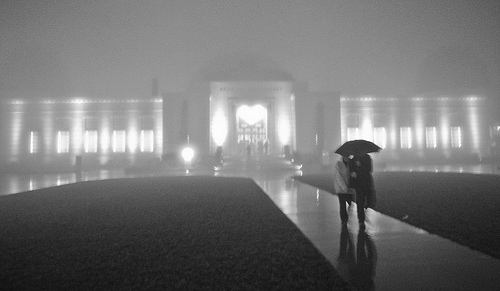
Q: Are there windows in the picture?
A: Yes, there is a window.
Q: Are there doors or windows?
A: Yes, there is a window.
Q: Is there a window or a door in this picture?
A: Yes, there is a window.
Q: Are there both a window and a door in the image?
A: Yes, there are both a window and a door.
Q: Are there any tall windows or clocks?
A: Yes, there is a tall window.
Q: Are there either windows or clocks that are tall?
A: Yes, the window is tall.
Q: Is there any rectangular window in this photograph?
A: Yes, there is a rectangular window.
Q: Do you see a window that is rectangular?
A: Yes, there is a window that is rectangular.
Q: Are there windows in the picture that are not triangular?
A: Yes, there is a rectangular window.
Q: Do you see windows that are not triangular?
A: Yes, there is a rectangular window.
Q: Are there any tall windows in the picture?
A: Yes, there is a tall window.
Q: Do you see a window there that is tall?
A: Yes, there is a window that is tall.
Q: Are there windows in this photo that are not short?
A: Yes, there is a tall window.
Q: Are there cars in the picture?
A: No, there are no cars.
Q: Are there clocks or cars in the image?
A: No, there are no cars or clocks.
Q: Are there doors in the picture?
A: Yes, there is a door.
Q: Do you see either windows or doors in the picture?
A: Yes, there is a door.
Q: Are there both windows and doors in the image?
A: Yes, there are both a door and a window.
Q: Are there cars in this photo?
A: No, there are no cars.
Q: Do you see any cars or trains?
A: No, there are no cars or trains.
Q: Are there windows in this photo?
A: Yes, there is a window.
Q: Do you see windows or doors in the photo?
A: Yes, there is a window.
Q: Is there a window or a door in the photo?
A: Yes, there is a window.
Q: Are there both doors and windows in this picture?
A: Yes, there are both a window and a door.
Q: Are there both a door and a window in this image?
A: Yes, there are both a window and a door.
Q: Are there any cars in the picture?
A: No, there are no cars.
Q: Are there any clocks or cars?
A: No, there are no cars or clocks.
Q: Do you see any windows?
A: Yes, there is a window.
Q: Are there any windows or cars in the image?
A: Yes, there is a window.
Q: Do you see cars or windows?
A: Yes, there is a window.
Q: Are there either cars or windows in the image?
A: Yes, there is a window.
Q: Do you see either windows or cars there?
A: Yes, there is a window.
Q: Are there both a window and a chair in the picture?
A: No, there is a window but no chairs.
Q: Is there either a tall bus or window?
A: Yes, there is a tall window.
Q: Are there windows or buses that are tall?
A: Yes, the window is tall.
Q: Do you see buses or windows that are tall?
A: Yes, the window is tall.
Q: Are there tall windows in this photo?
A: Yes, there is a tall window.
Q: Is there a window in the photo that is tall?
A: Yes, there is a window that is tall.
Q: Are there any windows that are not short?
A: Yes, there is a tall window.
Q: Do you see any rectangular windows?
A: Yes, there is a rectangular window.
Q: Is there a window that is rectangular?
A: Yes, there is a window that is rectangular.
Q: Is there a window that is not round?
A: Yes, there is a rectangular window.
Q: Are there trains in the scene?
A: No, there are no trains.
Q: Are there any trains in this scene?
A: No, there are no trains.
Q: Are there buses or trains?
A: No, there are no trains or buses.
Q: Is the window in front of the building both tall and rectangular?
A: Yes, the window is tall and rectangular.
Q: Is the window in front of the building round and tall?
A: No, the window is tall but rectangular.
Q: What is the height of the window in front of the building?
A: The window is tall.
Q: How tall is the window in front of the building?
A: The window is tall.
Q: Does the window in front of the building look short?
A: No, the window is tall.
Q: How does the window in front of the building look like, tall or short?
A: The window is tall.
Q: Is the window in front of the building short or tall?
A: The window is tall.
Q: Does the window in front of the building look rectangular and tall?
A: Yes, the window is rectangular and tall.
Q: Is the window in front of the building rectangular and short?
A: No, the window is rectangular but tall.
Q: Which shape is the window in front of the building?
A: The window is rectangular.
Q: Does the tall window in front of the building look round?
A: No, the window is rectangular.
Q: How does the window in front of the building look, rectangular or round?
A: The window is rectangular.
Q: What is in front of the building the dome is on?
A: The window is in front of the building.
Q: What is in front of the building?
A: The window is in front of the building.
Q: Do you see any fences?
A: No, there are no fences.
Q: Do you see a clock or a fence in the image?
A: No, there are no fences or clocks.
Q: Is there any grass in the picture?
A: Yes, there is grass.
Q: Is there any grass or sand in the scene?
A: Yes, there is grass.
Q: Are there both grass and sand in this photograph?
A: No, there is grass but no sand.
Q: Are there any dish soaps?
A: No, there are no dish soaps.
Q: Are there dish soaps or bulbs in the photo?
A: No, there are no dish soaps or bulbs.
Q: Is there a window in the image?
A: Yes, there is a window.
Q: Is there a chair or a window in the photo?
A: Yes, there is a window.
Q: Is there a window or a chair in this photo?
A: Yes, there is a window.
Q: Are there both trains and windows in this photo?
A: No, there is a window but no trains.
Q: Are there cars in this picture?
A: No, there are no cars.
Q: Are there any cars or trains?
A: No, there are no cars or trains.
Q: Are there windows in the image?
A: Yes, there is a window.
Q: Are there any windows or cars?
A: Yes, there is a window.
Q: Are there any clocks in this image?
A: No, there are no clocks.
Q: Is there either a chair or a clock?
A: No, there are no clocks or chairs.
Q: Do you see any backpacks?
A: No, there are no backpacks.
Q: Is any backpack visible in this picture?
A: No, there are no backpacks.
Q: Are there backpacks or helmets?
A: No, there are no backpacks or helmets.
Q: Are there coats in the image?
A: Yes, there is a coat.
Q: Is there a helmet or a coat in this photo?
A: Yes, there is a coat.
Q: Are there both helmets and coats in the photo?
A: No, there is a coat but no helmets.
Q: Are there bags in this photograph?
A: No, there are no bags.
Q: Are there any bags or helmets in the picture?
A: No, there are no bags or helmets.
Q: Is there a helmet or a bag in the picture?
A: No, there are no bags or helmets.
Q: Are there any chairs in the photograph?
A: No, there are no chairs.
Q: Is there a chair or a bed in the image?
A: No, there are no chairs or beds.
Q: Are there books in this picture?
A: No, there are no books.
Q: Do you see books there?
A: No, there are no books.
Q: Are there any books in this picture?
A: No, there are no books.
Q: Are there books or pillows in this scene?
A: No, there are no books or pillows.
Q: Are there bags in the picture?
A: No, there are no bags.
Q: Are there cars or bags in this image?
A: No, there are no bags or cars.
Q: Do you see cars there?
A: No, there are no cars.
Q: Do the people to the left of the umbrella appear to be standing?
A: Yes, the people are standing.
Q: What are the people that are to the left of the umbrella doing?
A: The people are standing.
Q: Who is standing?
A: The people are standing.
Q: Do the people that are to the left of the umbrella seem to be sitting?
A: No, the people are standing.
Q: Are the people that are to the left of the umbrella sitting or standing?
A: The people are standing.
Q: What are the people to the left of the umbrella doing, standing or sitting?
A: The people are standing.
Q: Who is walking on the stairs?
A: The people are walking on the stairs.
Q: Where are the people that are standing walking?
A: The people are walking on the stairs.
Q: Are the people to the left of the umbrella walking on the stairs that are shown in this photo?
A: Yes, the people are walking on the stairs.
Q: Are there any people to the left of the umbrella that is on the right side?
A: Yes, there are people to the left of the umbrella.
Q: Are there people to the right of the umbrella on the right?
A: No, the people are to the left of the umbrella.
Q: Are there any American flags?
A: No, there are no American flags.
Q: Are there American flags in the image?
A: No, there are no American flags.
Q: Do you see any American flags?
A: No, there are no American flags.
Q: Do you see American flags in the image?
A: No, there are no American flags.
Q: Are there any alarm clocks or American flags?
A: No, there are no American flags or alarm clocks.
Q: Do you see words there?
A: Yes, there are words.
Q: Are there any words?
A: Yes, there are words.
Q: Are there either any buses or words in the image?
A: Yes, there are words.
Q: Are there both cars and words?
A: No, there are words but no cars.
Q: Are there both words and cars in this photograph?
A: No, there are words but no cars.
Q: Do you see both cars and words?
A: No, there are words but no cars.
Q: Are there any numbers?
A: No, there are no numbers.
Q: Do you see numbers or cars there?
A: No, there are no numbers or cars.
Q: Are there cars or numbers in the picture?
A: No, there are no numbers or cars.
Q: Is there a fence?
A: No, there are no fences.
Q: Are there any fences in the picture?
A: No, there are no fences.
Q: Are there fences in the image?
A: No, there are no fences.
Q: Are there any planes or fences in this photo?
A: No, there are no fences or planes.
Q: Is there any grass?
A: Yes, there is grass.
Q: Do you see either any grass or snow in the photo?
A: Yes, there is grass.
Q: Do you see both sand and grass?
A: No, there is grass but no sand.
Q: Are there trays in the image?
A: No, there are no trays.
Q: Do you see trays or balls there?
A: No, there are no trays or balls.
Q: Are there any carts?
A: No, there are no carts.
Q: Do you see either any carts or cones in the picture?
A: No, there are no carts or cones.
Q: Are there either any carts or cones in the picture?
A: No, there are no carts or cones.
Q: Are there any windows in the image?
A: Yes, there is a window.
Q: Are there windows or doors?
A: Yes, there is a window.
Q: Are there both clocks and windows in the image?
A: No, there is a window but no clocks.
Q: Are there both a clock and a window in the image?
A: No, there is a window but no clocks.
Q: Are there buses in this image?
A: No, there are no buses.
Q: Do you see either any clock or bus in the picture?
A: No, there are no buses or clocks.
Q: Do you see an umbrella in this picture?
A: Yes, there is an umbrella.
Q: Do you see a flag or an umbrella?
A: Yes, there is an umbrella.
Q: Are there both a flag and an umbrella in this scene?
A: No, there is an umbrella but no flags.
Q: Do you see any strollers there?
A: No, there are no strollers.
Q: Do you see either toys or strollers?
A: No, there are no strollers or toys.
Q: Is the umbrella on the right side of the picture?
A: Yes, the umbrella is on the right of the image.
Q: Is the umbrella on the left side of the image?
A: No, the umbrella is on the right of the image.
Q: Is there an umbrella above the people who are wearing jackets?
A: Yes, there is an umbrella above the people.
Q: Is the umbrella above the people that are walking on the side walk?
A: Yes, the umbrella is above the people.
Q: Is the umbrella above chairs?
A: No, the umbrella is above the people.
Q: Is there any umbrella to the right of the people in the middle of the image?
A: Yes, there is an umbrella to the right of the people.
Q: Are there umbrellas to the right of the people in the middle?
A: Yes, there is an umbrella to the right of the people.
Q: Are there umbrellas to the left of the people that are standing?
A: No, the umbrella is to the right of the people.